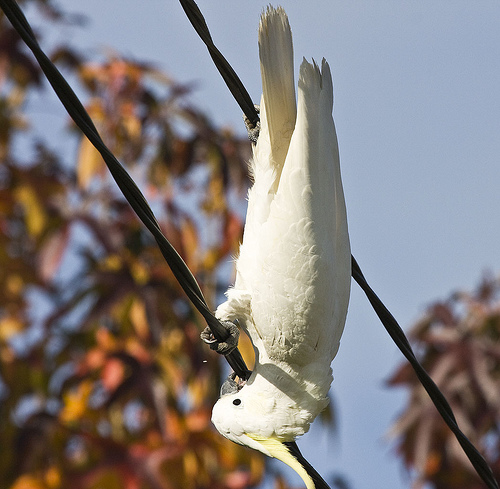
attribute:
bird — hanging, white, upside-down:
[195, 6, 352, 486]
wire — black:
[7, 1, 258, 129]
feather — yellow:
[251, 433, 322, 489]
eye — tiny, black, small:
[234, 399, 240, 406]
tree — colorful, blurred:
[5, 81, 242, 485]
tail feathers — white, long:
[256, 10, 342, 178]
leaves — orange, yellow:
[7, 302, 196, 485]